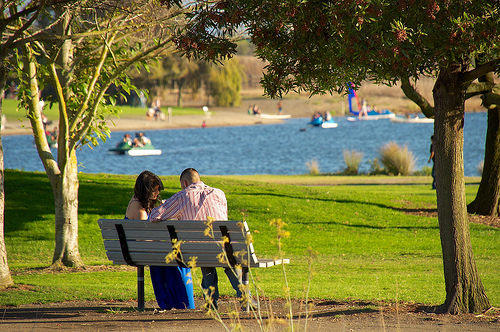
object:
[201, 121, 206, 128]
person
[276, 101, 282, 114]
person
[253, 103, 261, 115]
person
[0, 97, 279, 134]
beach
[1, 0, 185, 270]
tree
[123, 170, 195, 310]
dress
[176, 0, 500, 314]
tree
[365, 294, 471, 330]
dirt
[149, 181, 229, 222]
shirt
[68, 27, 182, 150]
tree branches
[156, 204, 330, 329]
weeds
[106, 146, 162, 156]
boat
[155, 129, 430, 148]
water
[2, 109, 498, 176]
water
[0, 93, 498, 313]
lawn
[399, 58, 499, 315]
trunk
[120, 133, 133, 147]
person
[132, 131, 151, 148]
person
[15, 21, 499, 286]
park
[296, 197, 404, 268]
grass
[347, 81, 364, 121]
raft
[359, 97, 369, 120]
person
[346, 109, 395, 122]
boat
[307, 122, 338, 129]
boat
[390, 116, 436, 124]
boat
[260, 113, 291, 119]
boat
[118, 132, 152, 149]
group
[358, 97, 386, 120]
group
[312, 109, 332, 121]
group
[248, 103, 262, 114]
group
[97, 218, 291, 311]
bench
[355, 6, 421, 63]
flowering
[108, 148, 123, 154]
raft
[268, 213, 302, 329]
weed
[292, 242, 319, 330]
weed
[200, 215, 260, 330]
weed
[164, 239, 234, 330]
weed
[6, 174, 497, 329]
ground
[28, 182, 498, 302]
sunshine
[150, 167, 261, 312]
man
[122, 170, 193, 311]
woman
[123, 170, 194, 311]
person